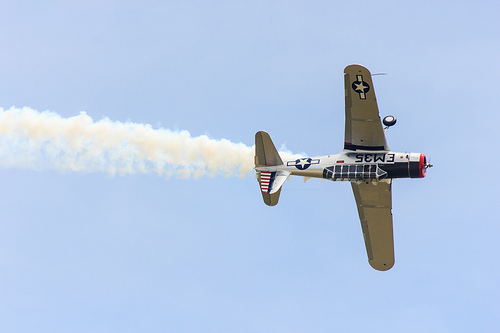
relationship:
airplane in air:
[253, 63, 421, 265] [225, 35, 297, 92]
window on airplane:
[369, 167, 379, 173] [253, 63, 421, 265]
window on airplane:
[345, 165, 353, 175] [253, 63, 421, 265]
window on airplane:
[336, 165, 344, 174] [253, 63, 421, 265]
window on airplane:
[325, 169, 328, 177] [253, 63, 421, 265]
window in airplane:
[358, 174, 361, 175] [253, 63, 421, 265]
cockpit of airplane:
[383, 169, 387, 181] [253, 63, 421, 265]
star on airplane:
[294, 155, 321, 172] [253, 63, 421, 265]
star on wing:
[351, 73, 369, 96] [350, 111, 377, 140]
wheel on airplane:
[381, 112, 398, 129] [253, 63, 421, 265]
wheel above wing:
[381, 112, 398, 129] [360, 193, 402, 272]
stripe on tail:
[263, 185, 269, 188] [257, 130, 283, 206]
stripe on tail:
[264, 178, 269, 181] [257, 130, 283, 206]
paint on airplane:
[420, 155, 424, 170] [253, 63, 421, 265]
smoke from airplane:
[23, 118, 61, 146] [253, 63, 421, 265]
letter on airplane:
[390, 153, 398, 166] [253, 63, 421, 265]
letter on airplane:
[376, 155, 387, 161] [253, 63, 421, 265]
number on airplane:
[356, 152, 360, 164] [253, 63, 421, 265]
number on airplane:
[368, 153, 372, 168] [253, 63, 421, 265]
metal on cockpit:
[337, 178, 343, 181] [383, 169, 387, 181]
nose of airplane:
[430, 163, 436, 170] [253, 63, 421, 265]